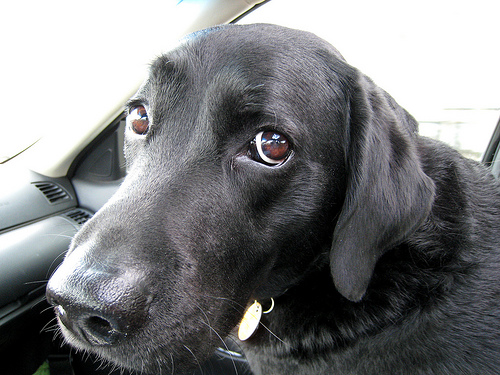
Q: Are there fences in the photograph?
A: No, there are no fences.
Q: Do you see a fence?
A: No, there are no fences.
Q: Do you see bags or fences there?
A: No, there are no fences or bags.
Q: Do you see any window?
A: Yes, there is a window.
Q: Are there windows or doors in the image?
A: Yes, there is a window.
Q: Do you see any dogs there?
A: Yes, there is a dog.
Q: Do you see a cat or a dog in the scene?
A: Yes, there is a dog.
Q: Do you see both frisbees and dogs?
A: No, there is a dog but no frisbees.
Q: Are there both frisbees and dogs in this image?
A: No, there is a dog but no frisbees.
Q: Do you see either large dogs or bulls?
A: Yes, there is a large dog.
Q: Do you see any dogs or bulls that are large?
A: Yes, the dog is large.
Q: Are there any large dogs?
A: Yes, there is a large dog.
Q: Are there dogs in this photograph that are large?
A: Yes, there is a dog that is large.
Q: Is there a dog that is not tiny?
A: Yes, there is a large dog.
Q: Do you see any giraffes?
A: No, there are no giraffes.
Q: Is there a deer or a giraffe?
A: No, there are no giraffes or deer.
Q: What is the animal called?
A: The animal is a dog.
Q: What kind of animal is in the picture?
A: The animal is a dog.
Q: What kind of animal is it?
A: The animal is a dog.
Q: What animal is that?
A: This is a dog.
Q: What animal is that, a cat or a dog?
A: This is a dog.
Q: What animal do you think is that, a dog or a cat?
A: This is a dog.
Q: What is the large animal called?
A: The animal is a dog.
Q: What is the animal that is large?
A: The animal is a dog.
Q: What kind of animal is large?
A: The animal is a dog.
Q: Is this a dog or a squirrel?
A: This is a dog.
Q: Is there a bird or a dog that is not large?
A: No, there is a dog but it is large.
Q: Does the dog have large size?
A: Yes, the dog is large.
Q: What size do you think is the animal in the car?
A: The dog is large.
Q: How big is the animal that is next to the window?
A: The dog is large.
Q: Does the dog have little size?
A: No, the dog is large.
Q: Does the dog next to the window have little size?
A: No, the dog is large.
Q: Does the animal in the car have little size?
A: No, the dog is large.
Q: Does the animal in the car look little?
A: No, the dog is large.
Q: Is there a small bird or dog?
A: No, there is a dog but it is large.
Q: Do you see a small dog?
A: No, there is a dog but it is large.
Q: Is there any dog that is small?
A: No, there is a dog but it is large.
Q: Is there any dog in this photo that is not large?
A: No, there is a dog but it is large.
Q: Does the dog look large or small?
A: The dog is large.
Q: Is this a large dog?
A: Yes, this is a large dog.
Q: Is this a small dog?
A: No, this is a large dog.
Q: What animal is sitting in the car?
A: The dog is sitting in the car.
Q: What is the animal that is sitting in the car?
A: The animal is a dog.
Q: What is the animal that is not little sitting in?
A: The dog is sitting in the car.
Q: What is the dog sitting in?
A: The dog is sitting in the car.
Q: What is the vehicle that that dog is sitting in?
A: The vehicle is a car.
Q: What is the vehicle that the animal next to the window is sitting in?
A: The vehicle is a car.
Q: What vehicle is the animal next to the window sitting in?
A: The dog is sitting in the car.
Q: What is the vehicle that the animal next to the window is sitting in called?
A: The vehicle is a car.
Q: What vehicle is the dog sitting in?
A: The dog is sitting in the car.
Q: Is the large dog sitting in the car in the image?
A: Yes, the dog is sitting in the car.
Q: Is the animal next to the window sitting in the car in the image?
A: Yes, the dog is sitting in the car.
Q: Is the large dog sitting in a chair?
A: No, the dog is sitting in the car.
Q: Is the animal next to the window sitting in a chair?
A: No, the dog is sitting in the car.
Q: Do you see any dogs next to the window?
A: Yes, there is a dog next to the window.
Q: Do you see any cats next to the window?
A: No, there is a dog next to the window.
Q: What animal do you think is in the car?
A: The dog is in the car.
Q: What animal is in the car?
A: The dog is in the car.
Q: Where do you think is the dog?
A: The dog is in the car.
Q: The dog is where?
A: The dog is in the car.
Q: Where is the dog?
A: The dog is in the car.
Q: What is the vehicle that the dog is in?
A: The vehicle is a car.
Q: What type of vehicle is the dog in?
A: The dog is in the car.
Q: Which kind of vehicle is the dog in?
A: The dog is in the car.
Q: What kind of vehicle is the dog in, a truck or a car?
A: The dog is in a car.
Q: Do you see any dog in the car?
A: Yes, there is a dog in the car.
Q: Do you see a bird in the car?
A: No, there is a dog in the car.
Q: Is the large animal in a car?
A: Yes, the dog is in a car.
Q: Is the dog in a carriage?
A: No, the dog is in a car.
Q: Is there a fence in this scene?
A: No, there are no fences.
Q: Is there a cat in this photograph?
A: No, there are no cats.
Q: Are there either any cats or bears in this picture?
A: No, there are no cats or bears.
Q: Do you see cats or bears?
A: No, there are no cats or bears.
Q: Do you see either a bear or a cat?
A: No, there are no cats or bears.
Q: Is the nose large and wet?
A: Yes, the nose is large and wet.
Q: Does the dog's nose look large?
A: Yes, the nose is large.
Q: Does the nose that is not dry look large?
A: Yes, the nose is large.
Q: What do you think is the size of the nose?
A: The nose is large.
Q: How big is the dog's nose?
A: The nose is large.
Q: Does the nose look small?
A: No, the nose is large.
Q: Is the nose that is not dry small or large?
A: The nose is large.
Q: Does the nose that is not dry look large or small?
A: The nose is large.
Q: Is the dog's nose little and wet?
A: No, the nose is wet but large.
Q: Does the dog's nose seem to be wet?
A: Yes, the nose is wet.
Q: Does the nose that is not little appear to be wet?
A: Yes, the nose is wet.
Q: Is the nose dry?
A: No, the nose is wet.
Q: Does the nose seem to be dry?
A: No, the nose is wet.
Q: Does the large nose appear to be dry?
A: No, the nose is wet.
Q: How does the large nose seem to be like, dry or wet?
A: The nose is wet.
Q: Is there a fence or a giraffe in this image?
A: No, there are no fences or giraffes.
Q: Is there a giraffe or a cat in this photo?
A: No, there are no giraffes or cats.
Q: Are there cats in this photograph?
A: No, there are no cats.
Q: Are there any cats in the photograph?
A: No, there are no cats.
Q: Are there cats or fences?
A: No, there are no cats or fences.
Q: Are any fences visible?
A: No, there are no fences.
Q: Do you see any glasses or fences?
A: No, there are no fences or glasses.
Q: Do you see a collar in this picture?
A: Yes, there is a collar.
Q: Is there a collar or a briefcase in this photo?
A: Yes, there is a collar.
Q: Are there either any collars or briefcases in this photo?
A: Yes, there is a collar.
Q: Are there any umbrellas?
A: No, there are no umbrellas.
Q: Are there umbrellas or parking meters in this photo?
A: No, there are no umbrellas or parking meters.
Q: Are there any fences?
A: No, there are no fences.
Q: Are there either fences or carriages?
A: No, there are no fences or carriages.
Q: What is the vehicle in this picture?
A: The vehicle is a car.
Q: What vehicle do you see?
A: The vehicle is a car.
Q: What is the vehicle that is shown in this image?
A: The vehicle is a car.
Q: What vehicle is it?
A: The vehicle is a car.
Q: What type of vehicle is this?
A: This is a car.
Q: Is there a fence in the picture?
A: No, there are no fences.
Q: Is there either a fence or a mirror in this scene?
A: No, there are no fences or mirrors.